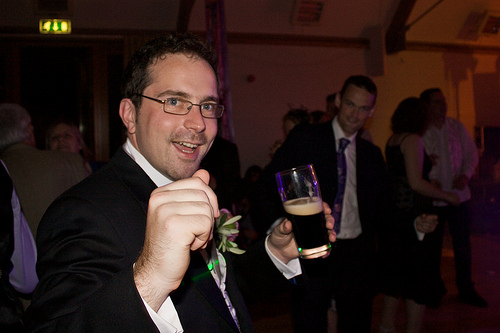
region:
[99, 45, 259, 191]
Man with glasses.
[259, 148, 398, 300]
Man with a beer in his hand.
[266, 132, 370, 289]
Man with a dark beer.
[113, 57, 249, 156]
Man with glasses on his face.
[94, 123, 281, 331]
Man with a tie.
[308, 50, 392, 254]
Man with a tie on his white shirt.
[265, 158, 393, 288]
Glass with beer in it.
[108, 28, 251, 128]
Man with brunette hair.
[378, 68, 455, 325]
Woman with a dress on.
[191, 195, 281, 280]
Flower on the man's shirt.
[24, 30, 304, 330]
A man wearing a suit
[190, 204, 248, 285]
Corsage on a suit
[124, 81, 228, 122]
A pair of eyeglasses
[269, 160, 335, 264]
Beverage in a glass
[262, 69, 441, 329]
Man wearing a suit and tie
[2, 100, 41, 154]
White hair on man's head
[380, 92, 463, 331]
Woman wearing a black dress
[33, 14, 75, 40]
A green and yellow sign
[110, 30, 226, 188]
The man is smiling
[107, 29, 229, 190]
Brown hair on man's head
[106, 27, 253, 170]
head of the person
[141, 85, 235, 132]
glasses on the person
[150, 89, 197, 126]
frame of the glasses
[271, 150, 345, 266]
glass in man's hand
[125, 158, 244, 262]
right hand of man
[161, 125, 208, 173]
mouth of the man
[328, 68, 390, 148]
head of a man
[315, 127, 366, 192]
tie on the shirt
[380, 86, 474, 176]
people in the background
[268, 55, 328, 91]
wall in the background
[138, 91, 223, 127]
The eyeglasses the man is wearing.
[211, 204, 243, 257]
The carnation on the man's suit jacket.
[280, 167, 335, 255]
The glass in the man's hand.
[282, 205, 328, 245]
The brown liquid in the man's glass.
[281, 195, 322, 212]
The froth at the top of the liquid in the glass.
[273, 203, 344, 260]
The man's hand holding the glass.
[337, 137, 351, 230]
The tie the man is wearing.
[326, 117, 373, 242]
The white shirt the man in the tie is wearing.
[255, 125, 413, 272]
The blazer the man in the tie is wearing.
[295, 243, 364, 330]
The pants the man wearing the tie has on.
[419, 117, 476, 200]
The white shirt the man is wearing standing next to the lady in the dress.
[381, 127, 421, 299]
The black dress the lady is wearing.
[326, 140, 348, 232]
The tie the man is wearing.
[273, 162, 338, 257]
The glass the man is holding.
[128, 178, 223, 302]
The man's left hand that is wearing glasses.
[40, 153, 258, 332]
The black jacket the man in glasses is wearing.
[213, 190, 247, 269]
The flower on the man's blazer.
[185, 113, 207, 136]
The nose of the man that is wearing the glasses.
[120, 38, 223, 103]
The short hair of the man that is wearing the glasses.